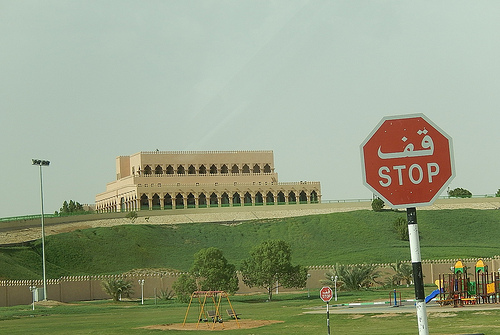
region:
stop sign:
[363, 114, 467, 246]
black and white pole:
[404, 212, 435, 332]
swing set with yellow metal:
[174, 283, 244, 332]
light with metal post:
[22, 153, 65, 308]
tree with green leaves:
[235, 248, 313, 330]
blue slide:
[428, 276, 442, 309]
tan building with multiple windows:
[102, 134, 327, 216]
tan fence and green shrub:
[56, 274, 131, 301]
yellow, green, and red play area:
[441, 256, 497, 315]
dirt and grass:
[374, 311, 412, 325]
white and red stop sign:
[363, 112, 462, 333]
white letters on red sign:
[375, 130, 440, 189]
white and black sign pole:
[404, 205, 429, 333]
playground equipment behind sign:
[176, 257, 499, 334]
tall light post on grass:
[28, 157, 60, 305]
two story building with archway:
[94, 146, 321, 221]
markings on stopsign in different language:
[373, 129, 436, 159]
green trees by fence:
[96, 242, 416, 304]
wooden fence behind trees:
[0, 255, 498, 306]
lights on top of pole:
[31, 158, 50, 166]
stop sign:
[358, 106, 463, 213]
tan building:
[72, 129, 323, 214]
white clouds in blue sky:
[58, 48, 122, 82]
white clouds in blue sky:
[407, 12, 447, 37]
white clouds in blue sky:
[434, 43, 498, 104]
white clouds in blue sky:
[348, 19, 408, 44]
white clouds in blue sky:
[260, 102, 335, 129]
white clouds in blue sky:
[310, 35, 362, 77]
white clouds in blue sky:
[131, 45, 176, 75]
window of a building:
[262, 163, 280, 178]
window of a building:
[251, 158, 261, 183]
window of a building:
[238, 157, 253, 176]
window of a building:
[220, 159, 242, 176]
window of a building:
[204, 159, 219, 173]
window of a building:
[193, 158, 208, 178]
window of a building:
[174, 159, 204, 180]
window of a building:
[146, 160, 176, 175]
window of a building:
[140, 188, 165, 212]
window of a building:
[170, 191, 196, 213]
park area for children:
[0, 256, 499, 333]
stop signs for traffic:
[313, 109, 468, 333]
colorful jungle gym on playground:
[421, 256, 498, 306]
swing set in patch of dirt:
[178, 286, 242, 329]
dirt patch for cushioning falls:
[129, 312, 290, 334]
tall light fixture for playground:
[27, 152, 57, 307]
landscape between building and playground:
[1, 195, 499, 280]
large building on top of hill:
[88, 151, 323, 211]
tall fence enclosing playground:
[0, 253, 499, 306]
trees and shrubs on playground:
[96, 236, 421, 301]